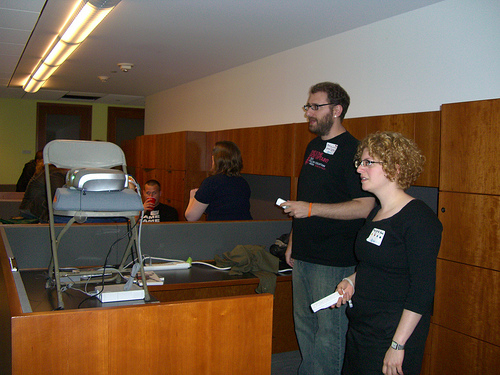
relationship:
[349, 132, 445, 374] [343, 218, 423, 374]
woman in clothing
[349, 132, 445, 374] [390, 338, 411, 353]
woman wearing watch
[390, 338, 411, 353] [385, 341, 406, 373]
watch on hand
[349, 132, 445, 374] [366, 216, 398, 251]
woman has name tag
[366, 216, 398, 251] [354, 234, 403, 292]
name tag on vest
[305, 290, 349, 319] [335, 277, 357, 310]
controller in hand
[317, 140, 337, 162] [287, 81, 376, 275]
name tag on gamers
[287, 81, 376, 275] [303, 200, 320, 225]
gamers has wristband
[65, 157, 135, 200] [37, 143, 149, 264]
projector on chair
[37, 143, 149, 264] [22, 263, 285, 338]
chair on desk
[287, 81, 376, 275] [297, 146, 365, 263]
gamers wearing shirt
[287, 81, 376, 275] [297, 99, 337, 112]
gamers wearing glasses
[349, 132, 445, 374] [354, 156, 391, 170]
woman wearing glasses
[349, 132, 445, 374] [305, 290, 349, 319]
woman holding controller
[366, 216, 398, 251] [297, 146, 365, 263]
name tag on shirt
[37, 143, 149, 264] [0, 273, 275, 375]
chair on desk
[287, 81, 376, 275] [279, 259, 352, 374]
gamers wearing jeans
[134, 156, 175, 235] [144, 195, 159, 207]
man has cup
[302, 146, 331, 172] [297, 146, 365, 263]
words on shirt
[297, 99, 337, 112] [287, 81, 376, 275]
glasses on gamers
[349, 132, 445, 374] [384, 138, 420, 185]
woman has hair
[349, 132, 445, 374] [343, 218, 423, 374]
lady wearing dress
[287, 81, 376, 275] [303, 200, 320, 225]
gamers wearing armband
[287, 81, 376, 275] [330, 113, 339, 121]
gamers wearing earring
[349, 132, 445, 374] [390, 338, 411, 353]
lady wearing watch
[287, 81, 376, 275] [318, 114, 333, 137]
gamers has beard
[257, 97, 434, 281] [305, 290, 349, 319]
gamers with controller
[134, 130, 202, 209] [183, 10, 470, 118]
cabinets on wall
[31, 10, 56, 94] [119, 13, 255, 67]
light fixture on ceiling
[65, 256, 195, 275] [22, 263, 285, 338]
surge protector on desk